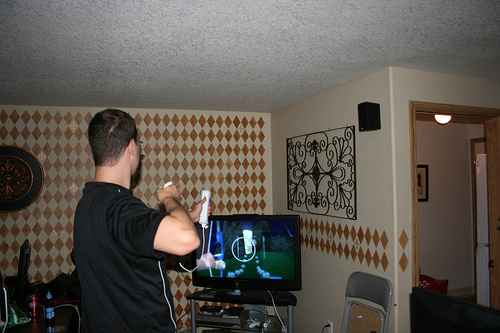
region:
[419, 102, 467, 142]
the light is on the ceiling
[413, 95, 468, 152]
the light is on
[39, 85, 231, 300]
the man is holding remotes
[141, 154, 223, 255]
the remote is white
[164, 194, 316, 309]
the television is black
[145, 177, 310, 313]
the television is on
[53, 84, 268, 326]
the man is playing a game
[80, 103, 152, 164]
the man is wearing glasses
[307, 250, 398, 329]
the chair is closed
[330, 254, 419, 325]
the chair is leaning against the wall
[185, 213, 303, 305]
a flat screen TV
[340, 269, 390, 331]
a grey folding chair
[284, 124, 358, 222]
a piece of black metal art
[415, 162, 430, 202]
a framed art print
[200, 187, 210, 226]
a Wii video game controller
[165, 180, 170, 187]
a Wii video game controller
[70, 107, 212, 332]
a man playing a video game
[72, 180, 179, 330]
a black shirt with white stripe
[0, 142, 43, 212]
a piece of brass wall art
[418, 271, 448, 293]
a red plastic container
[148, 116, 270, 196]
Diamond pattern on a white wall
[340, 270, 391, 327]
Steel chair against a wall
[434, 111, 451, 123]
Light fixture on a ceiling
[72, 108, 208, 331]
A man in a black shirt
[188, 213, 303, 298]
A black television on a stand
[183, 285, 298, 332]
A black television stand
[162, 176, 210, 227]
A Nintendo Wii remote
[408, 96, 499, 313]
A wooden sill on a doorway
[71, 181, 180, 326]
Black shirt on a man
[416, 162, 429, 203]
A framed picture on the wall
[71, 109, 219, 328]
man playing with wii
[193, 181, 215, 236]
remote in man's hand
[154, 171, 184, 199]
remote in man's hand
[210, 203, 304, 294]
tv in the corner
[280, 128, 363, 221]
decoration on the wall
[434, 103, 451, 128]
light on the ceiling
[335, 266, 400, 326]
chair against the wall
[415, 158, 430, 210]
picture on the wall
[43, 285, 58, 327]
bottle on the table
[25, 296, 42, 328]
can on the table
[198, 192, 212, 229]
he's holding the controller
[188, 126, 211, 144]
the wall has triangles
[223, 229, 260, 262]
the tv is on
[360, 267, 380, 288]
chair is leaning on the wall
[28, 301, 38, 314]
the can is red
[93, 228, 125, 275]
the shirt is black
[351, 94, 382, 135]
speaker is on the wall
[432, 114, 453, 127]
the light is on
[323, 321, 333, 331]
the cord is plugged in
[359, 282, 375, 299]
the chair is gray